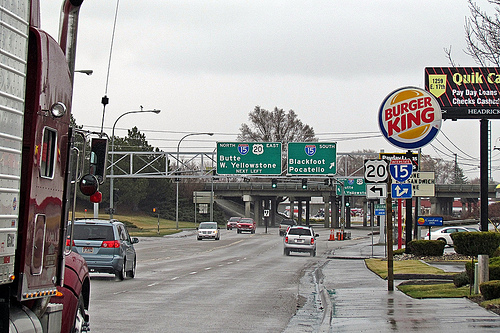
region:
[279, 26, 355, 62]
the sky is blue in color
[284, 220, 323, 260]
this is a car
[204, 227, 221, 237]
the car is white in color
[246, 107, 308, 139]
this is a tree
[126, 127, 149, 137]
the leaves are green in color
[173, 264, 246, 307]
this is the road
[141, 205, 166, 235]
this is a grass area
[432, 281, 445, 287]
the grass is green in color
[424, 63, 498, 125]
a billboard next to the street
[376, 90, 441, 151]
a burger king sign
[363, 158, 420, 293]
street signs on a wooden post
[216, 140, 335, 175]
street signs above the road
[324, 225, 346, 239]
orange traffic cones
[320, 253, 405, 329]
the sidewalk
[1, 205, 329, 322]
cars driving on the road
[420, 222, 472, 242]
a white car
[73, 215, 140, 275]
a blue mini van driving on the road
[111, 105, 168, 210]
a street light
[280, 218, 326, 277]
This is a car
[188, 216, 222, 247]
This is a car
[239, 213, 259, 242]
This is a car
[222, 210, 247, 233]
This is a car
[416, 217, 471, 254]
This is a car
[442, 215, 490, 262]
This is a car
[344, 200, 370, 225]
This is a car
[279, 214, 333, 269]
This is a car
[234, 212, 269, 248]
This is a car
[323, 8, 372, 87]
the sky is blue in color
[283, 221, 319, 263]
this is a car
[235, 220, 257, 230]
the car is red in color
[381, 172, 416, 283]
this is a pole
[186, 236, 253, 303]
this is the road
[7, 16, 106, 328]
this is a lorry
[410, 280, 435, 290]
this is a grass area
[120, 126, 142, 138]
the leaves are green in color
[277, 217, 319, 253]
this is a car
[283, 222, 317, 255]
the car is moving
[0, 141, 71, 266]
this is a trailer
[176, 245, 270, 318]
this is a road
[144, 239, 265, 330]
the road is tarmacked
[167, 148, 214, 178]
this is the bridge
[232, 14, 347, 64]
this is the sky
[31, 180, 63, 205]
the trailer is red in color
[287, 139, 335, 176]
the poster is green in color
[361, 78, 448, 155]
Burger King sign on pole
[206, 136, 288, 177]
Green sign over road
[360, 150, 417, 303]
Road signs on a pole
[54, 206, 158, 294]
Silver van driving on street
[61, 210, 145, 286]
Silver van driving down road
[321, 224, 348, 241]
Orange cones on the road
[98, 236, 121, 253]
Taillight of a van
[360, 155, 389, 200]
Black and white sign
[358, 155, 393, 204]
Black and white sign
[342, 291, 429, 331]
Puddles on the sidewalk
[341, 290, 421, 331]
Puddles on the concrete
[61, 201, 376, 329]
Cars driving on the road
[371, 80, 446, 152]
A round Burger King sign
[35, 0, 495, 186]
The sky appears very cloudy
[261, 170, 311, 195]
Two traffic lights are green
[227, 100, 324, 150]
The top of a tree